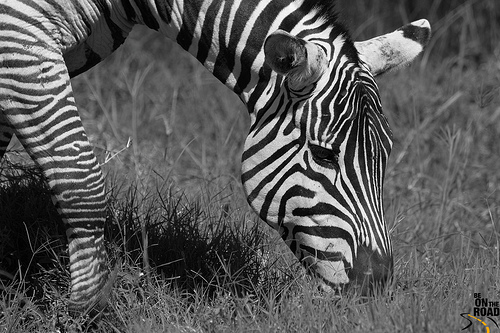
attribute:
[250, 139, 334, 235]
stripes — black, white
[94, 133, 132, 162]
grass — yellow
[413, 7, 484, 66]
grass — yellow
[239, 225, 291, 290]
grass — yellow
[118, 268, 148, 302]
grass — yellow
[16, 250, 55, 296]
grass — yellow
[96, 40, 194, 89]
grass — yellow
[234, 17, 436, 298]
head — black, grey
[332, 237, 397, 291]
nose — grey, black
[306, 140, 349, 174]
eye — black, grey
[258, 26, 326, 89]
ear — grey, black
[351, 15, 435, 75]
ear — black, grey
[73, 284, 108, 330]
feet — black, grey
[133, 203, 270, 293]
shadow — grey, black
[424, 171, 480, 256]
grass — black, white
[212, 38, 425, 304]
zebra — grey, white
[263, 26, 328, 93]
ear — white, grey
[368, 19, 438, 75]
ear — grey, white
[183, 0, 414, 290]
zebra — black, grey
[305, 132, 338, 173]
eye — white, grey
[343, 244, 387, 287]
nose — grey, white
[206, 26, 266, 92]
neck — white, grey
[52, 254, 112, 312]
feet — grey, white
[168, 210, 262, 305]
grass — grey, tall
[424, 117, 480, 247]
grass — tall, grey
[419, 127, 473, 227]
grass — grey, tall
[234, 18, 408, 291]
zebra — black, grey